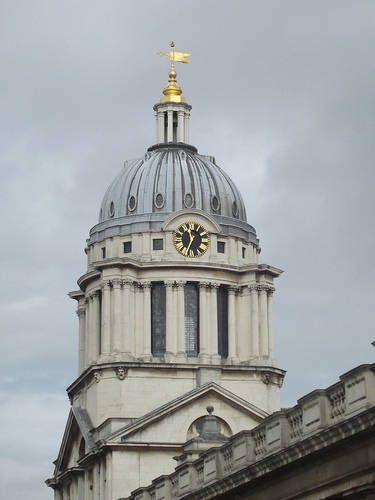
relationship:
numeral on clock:
[187, 221, 195, 230] [174, 220, 210, 260]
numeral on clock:
[196, 229, 206, 239] [174, 220, 210, 260]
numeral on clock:
[200, 236, 210, 245] [174, 220, 210, 260]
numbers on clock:
[190, 248, 194, 256] [174, 220, 210, 260]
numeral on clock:
[180, 245, 190, 258] [174, 220, 210, 260]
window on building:
[183, 279, 198, 356] [42, 36, 373, 497]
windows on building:
[145, 275, 236, 365] [42, 36, 373, 497]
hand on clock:
[187, 235, 196, 251] [171, 220, 211, 260]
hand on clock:
[185, 227, 194, 240] [171, 220, 211, 260]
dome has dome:
[84, 142, 261, 251] [89, 138, 250, 225]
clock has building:
[173, 221, 211, 258] [42, 36, 373, 497]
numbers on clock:
[190, 248, 194, 256] [171, 220, 211, 260]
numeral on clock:
[188, 221, 195, 230] [173, 221, 211, 258]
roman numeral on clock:
[194, 222, 203, 233] [173, 221, 211, 258]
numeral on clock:
[199, 229, 206, 236] [173, 221, 211, 258]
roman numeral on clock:
[199, 242, 207, 251] [173, 221, 211, 258]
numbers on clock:
[190, 248, 194, 256] [173, 221, 211, 258]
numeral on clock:
[199, 229, 206, 236] [164, 206, 217, 267]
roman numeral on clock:
[173, 236, 182, 240] [173, 221, 210, 257]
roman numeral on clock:
[180, 224, 188, 232] [173, 221, 210, 257]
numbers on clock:
[176, 241, 185, 249] [173, 221, 210, 257]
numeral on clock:
[188, 221, 195, 230] [173, 221, 210, 257]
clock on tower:
[173, 221, 211, 258] [56, 17, 298, 403]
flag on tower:
[152, 42, 197, 65] [56, 17, 298, 403]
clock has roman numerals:
[171, 220, 211, 260] [174, 223, 206, 255]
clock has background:
[173, 221, 211, 258] [176, 224, 209, 256]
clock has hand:
[173, 221, 211, 258] [187, 227, 194, 240]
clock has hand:
[173, 221, 211, 258] [184, 233, 194, 255]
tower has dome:
[44, 39, 287, 500] [84, 142, 261, 251]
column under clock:
[139, 279, 151, 364] [170, 215, 224, 276]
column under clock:
[165, 277, 178, 360] [170, 215, 224, 276]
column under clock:
[172, 279, 186, 366] [170, 215, 224, 276]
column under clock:
[196, 279, 210, 367] [170, 215, 224, 276]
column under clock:
[207, 279, 224, 363] [170, 215, 224, 276]